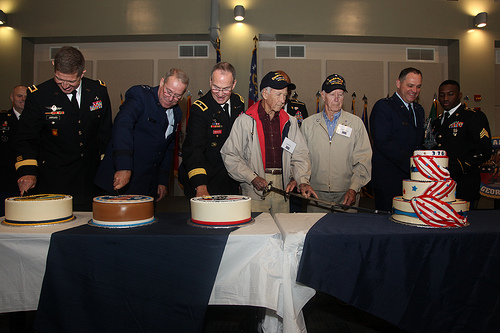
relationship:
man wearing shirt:
[286, 73, 371, 215] [321, 111, 340, 141]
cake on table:
[392, 149, 470, 225] [2, 197, 498, 322]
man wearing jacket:
[96, 67, 185, 202] [97, 86, 185, 194]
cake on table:
[92, 194, 155, 227] [25, 212, 477, 317]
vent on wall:
[278, 41, 308, 56] [328, 12, 405, 30]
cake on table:
[392, 149, 470, 225] [3, 220, 497, 320]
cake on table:
[179, 177, 274, 232] [3, 220, 497, 320]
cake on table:
[88, 185, 154, 227] [3, 220, 497, 320]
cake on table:
[4, 185, 79, 230] [3, 220, 497, 320]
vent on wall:
[177, 42, 209, 59] [0, 4, 498, 139]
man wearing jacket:
[220, 69, 319, 213] [227, 127, 258, 167]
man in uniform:
[9, 47, 112, 211] [10, 77, 120, 209]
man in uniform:
[9, 47, 112, 211] [13, 79, 114, 203]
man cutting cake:
[9, 47, 112, 211] [178, 175, 266, 233]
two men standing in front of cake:
[384, 49, 498, 229] [397, 136, 471, 232]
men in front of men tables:
[8, 40, 498, 207] [0, 208, 500, 333]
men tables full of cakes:
[0, 208, 500, 333] [0, 146, 468, 240]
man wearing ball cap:
[220, 69, 319, 213] [318, 71, 349, 95]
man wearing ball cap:
[286, 73, 371, 215] [255, 68, 297, 90]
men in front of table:
[8, 40, 498, 207] [2, 197, 498, 322]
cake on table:
[392, 149, 470, 225] [4, 206, 498, 309]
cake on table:
[190, 195, 252, 226] [4, 206, 498, 309]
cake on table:
[92, 194, 155, 227] [4, 206, 498, 309]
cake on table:
[4, 193, 75, 226] [4, 206, 498, 309]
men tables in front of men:
[0, 208, 500, 333] [0, 42, 500, 195]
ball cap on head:
[321, 73, 348, 93] [321, 83, 346, 113]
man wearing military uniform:
[428, 80, 492, 208] [420, 107, 487, 179]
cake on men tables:
[391, 149, 468, 226] [0, 208, 500, 333]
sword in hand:
[255, 178, 387, 218] [339, 188, 360, 211]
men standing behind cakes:
[8, 40, 498, 207] [3, 147, 497, 251]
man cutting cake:
[221, 65, 319, 213] [392, 149, 470, 225]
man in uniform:
[428, 80, 492, 208] [439, 107, 494, 204]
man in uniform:
[177, 61, 245, 212] [322, 72, 343, 89]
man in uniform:
[9, 47, 112, 211] [264, 71, 293, 86]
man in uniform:
[286, 73, 371, 215] [185, 100, 240, 192]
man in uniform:
[220, 69, 319, 213] [18, 91, 110, 194]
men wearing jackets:
[8, 40, 498, 207] [218, 104, 378, 196]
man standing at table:
[286, 73, 371, 215] [2, 197, 498, 322]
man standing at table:
[366, 67, 427, 207] [2, 197, 498, 322]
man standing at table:
[427, 80, 494, 207] [2, 197, 498, 322]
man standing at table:
[220, 69, 319, 213] [2, 197, 498, 322]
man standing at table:
[177, 62, 243, 211] [2, 197, 498, 322]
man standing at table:
[95, 68, 189, 214] [2, 197, 498, 322]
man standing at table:
[10, 42, 115, 217] [2, 197, 498, 322]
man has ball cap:
[286, 73, 371, 215] [321, 73, 348, 93]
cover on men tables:
[329, 213, 446, 313] [0, 208, 500, 333]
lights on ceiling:
[227, 6, 494, 33] [107, 13, 190, 51]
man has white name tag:
[292, 70, 374, 209] [330, 116, 356, 151]